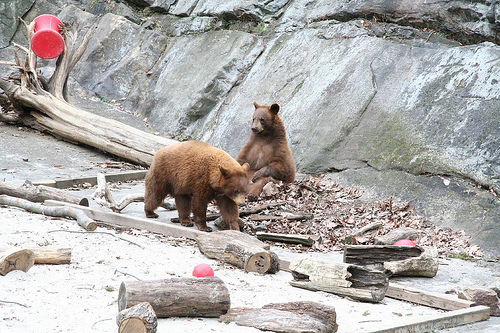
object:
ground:
[0, 65, 500, 333]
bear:
[143, 140, 250, 232]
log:
[115, 301, 161, 333]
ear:
[216, 164, 230, 177]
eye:
[260, 117, 265, 121]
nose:
[251, 126, 259, 132]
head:
[215, 162, 250, 208]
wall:
[1, 0, 500, 263]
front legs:
[191, 193, 212, 227]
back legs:
[143, 168, 170, 214]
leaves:
[321, 218, 337, 229]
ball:
[192, 263, 215, 277]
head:
[250, 101, 279, 135]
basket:
[29, 13, 65, 60]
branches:
[9, 40, 29, 55]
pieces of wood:
[217, 301, 338, 333]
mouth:
[250, 126, 261, 133]